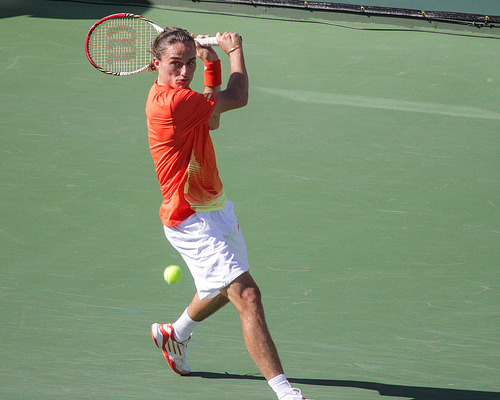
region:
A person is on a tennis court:
[30, 11, 480, 397]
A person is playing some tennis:
[55, 5, 463, 398]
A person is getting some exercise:
[33, 13, 474, 398]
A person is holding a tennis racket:
[42, 18, 492, 388]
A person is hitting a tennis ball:
[22, 5, 475, 393]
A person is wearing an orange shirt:
[46, 18, 491, 384]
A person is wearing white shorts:
[45, 8, 486, 389]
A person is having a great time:
[35, 13, 498, 388]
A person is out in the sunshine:
[25, 11, 488, 386]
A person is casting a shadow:
[55, 4, 499, 399]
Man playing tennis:
[80, 12, 312, 399]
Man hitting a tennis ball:
[80, 10, 309, 397]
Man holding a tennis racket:
[82, 11, 315, 398]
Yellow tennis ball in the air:
[159, 261, 184, 287]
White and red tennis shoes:
[149, 318, 194, 378]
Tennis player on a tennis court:
[80, 10, 317, 399]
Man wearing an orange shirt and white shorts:
[142, 28, 313, 399]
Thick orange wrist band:
[199, 55, 224, 87]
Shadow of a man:
[179, 363, 499, 399]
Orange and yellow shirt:
[145, 75, 229, 229]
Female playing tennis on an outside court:
[75, 10, 302, 396]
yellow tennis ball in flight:
[158, 264, 189, 288]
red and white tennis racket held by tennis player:
[83, 10, 245, 78]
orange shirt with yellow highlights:
[137, 77, 232, 232]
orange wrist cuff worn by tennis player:
[195, 51, 224, 95]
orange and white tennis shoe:
[145, 317, 200, 382]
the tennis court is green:
[272, 106, 323, 248]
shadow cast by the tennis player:
[186, 365, 497, 398]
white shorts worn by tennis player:
[151, 198, 266, 304]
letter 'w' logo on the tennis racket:
[102, 22, 140, 65]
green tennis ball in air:
[146, 267, 183, 282]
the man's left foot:
[149, 322, 195, 376]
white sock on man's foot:
[268, 371, 292, 397]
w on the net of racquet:
[107, 25, 138, 65]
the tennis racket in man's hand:
[84, 11, 230, 81]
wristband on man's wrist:
[199, 58, 226, 88]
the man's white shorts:
[164, 195, 267, 300]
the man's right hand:
[218, 29, 244, 50]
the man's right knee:
[229, 279, 265, 309]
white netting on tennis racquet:
[88, 19, 153, 69]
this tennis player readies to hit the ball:
[79, 10, 314, 399]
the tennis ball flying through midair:
[156, 257, 188, 291]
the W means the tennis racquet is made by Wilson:
[80, 10, 239, 82]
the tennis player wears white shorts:
[156, 185, 258, 300]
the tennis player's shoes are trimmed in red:
[146, 315, 197, 379]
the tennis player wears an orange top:
[141, 75, 231, 233]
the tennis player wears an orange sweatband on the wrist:
[197, 52, 224, 88]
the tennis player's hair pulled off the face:
[143, 22, 201, 87]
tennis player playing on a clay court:
[3, 82, 496, 399]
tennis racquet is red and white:
[82, 8, 233, 78]